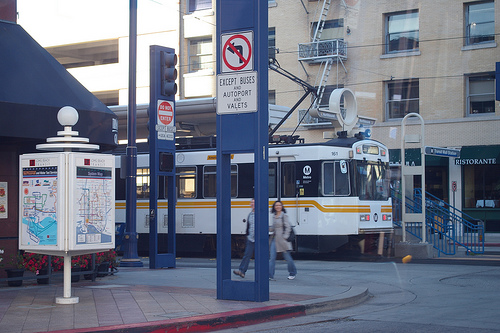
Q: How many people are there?
A: Two.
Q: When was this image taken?
A: Daytime.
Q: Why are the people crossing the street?
A: To get to the other side.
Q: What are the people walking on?
A: The street.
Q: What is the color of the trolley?
A: White.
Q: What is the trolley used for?
A: Transportation.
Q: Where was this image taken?
A: At an intersection.